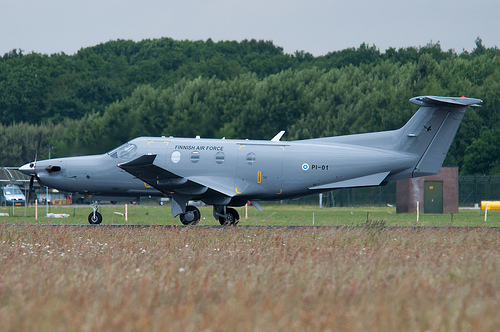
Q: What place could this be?
A: It is a forest.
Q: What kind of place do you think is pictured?
A: It is a forest.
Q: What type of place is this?
A: It is a forest.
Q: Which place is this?
A: It is a forest.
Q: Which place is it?
A: It is a forest.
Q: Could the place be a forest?
A: Yes, it is a forest.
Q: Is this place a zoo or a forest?
A: It is a forest.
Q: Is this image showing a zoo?
A: No, the picture is showing a forest.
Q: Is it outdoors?
A: Yes, it is outdoors.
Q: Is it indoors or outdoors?
A: It is outdoors.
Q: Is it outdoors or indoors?
A: It is outdoors.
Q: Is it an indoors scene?
A: No, it is outdoors.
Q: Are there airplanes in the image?
A: Yes, there is an airplane.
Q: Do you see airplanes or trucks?
A: Yes, there is an airplane.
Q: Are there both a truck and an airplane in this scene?
A: No, there is an airplane but no trucks.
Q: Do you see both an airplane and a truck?
A: No, there is an airplane but no trucks.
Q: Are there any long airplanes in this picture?
A: Yes, there is a long airplane.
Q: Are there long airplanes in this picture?
A: Yes, there is a long airplane.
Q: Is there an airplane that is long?
A: Yes, there is an airplane that is long.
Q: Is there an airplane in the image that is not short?
A: Yes, there is a long airplane.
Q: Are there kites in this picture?
A: No, there are no kites.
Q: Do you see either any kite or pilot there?
A: No, there are no kites or pilots.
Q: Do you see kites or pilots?
A: No, there are no kites or pilots.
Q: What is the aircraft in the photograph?
A: The aircraft is an airplane.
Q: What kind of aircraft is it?
A: The aircraft is an airplane.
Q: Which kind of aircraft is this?
A: That is an airplane.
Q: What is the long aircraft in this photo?
A: The aircraft is an airplane.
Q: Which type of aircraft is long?
A: The aircraft is an airplane.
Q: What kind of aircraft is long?
A: The aircraft is an airplane.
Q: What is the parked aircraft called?
A: The aircraft is an airplane.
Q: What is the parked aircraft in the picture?
A: The aircraft is an airplane.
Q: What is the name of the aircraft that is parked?
A: The aircraft is an airplane.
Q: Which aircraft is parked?
A: The aircraft is an airplane.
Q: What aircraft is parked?
A: The aircraft is an airplane.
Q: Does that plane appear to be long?
A: Yes, the plane is long.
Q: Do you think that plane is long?
A: Yes, the plane is long.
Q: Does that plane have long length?
A: Yes, the plane is long.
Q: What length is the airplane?
A: The airplane is long.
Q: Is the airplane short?
A: No, the airplane is long.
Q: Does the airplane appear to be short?
A: No, the airplane is long.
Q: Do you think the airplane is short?
A: No, the airplane is long.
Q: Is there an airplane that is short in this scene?
A: No, there is an airplane but it is long.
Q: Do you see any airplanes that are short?
A: No, there is an airplane but it is long.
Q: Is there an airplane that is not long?
A: No, there is an airplane but it is long.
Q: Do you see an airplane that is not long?
A: No, there is an airplane but it is long.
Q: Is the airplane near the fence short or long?
A: The plane is long.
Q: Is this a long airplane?
A: Yes, this is a long airplane.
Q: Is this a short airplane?
A: No, this is a long airplane.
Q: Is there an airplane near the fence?
A: Yes, there is an airplane near the fence.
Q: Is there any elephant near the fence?
A: No, there is an airplane near the fence.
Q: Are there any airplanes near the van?
A: Yes, there is an airplane near the van.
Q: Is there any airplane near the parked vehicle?
A: Yes, there is an airplane near the van.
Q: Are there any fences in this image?
A: Yes, there is a fence.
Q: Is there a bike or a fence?
A: Yes, there is a fence.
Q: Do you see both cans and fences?
A: No, there is a fence but no cans.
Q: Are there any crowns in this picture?
A: No, there are no crowns.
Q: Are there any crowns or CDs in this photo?
A: No, there are no crowns or cds.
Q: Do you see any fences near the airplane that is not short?
A: Yes, there is a fence near the airplane.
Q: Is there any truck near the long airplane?
A: No, there is a fence near the plane.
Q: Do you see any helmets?
A: No, there are no helmets.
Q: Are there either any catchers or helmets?
A: No, there are no helmets or catchers.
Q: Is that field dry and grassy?
A: Yes, the field is dry and grassy.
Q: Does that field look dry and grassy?
A: Yes, the field is dry and grassy.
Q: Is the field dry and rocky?
A: No, the field is dry but grassy.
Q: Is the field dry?
A: Yes, the field is dry.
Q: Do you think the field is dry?
A: Yes, the field is dry.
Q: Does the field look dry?
A: Yes, the field is dry.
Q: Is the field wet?
A: No, the field is dry.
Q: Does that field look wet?
A: No, the field is dry.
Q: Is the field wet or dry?
A: The field is dry.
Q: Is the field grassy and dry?
A: Yes, the field is grassy and dry.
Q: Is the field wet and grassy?
A: No, the field is grassy but dry.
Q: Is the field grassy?
A: Yes, the field is grassy.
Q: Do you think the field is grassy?
A: Yes, the field is grassy.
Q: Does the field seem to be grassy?
A: Yes, the field is grassy.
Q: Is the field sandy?
A: No, the field is grassy.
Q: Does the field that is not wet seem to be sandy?
A: No, the field is grassy.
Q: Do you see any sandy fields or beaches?
A: No, there is a field but it is grassy.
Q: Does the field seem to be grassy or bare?
A: The field is grassy.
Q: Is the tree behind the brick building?
A: Yes, the tree is behind the building.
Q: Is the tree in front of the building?
A: No, the tree is behind the building.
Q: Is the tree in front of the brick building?
A: No, the tree is behind the building.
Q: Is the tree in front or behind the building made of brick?
A: The tree is behind the building.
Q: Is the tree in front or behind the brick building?
A: The tree is behind the building.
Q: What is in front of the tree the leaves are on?
A: The building is in front of the tree.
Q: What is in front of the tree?
A: The building is in front of the tree.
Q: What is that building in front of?
A: The building is in front of the tree.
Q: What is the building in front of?
A: The building is in front of the tree.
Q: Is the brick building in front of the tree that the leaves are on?
A: Yes, the building is in front of the tree.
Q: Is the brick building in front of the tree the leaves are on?
A: Yes, the building is in front of the tree.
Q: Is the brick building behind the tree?
A: No, the building is in front of the tree.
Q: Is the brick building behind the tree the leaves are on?
A: No, the building is in front of the tree.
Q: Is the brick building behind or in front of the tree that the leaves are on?
A: The building is in front of the tree.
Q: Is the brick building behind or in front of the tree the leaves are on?
A: The building is in front of the tree.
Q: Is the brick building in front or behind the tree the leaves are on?
A: The building is in front of the tree.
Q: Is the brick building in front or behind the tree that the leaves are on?
A: The building is in front of the tree.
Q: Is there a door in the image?
A: Yes, there is a door.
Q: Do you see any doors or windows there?
A: Yes, there is a door.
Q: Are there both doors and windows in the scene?
A: Yes, there are both a door and a window.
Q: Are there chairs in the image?
A: No, there are no chairs.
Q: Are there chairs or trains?
A: No, there are no chairs or trains.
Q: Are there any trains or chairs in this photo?
A: No, there are no chairs or trains.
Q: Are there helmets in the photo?
A: No, there are no helmets.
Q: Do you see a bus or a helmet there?
A: No, there are no helmets or buses.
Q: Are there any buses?
A: No, there are no buses.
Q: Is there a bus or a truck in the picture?
A: No, there are no buses or trucks.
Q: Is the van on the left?
A: Yes, the van is on the left of the image.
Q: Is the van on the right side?
A: No, the van is on the left of the image.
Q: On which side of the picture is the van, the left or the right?
A: The van is on the left of the image.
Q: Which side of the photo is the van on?
A: The van is on the left of the image.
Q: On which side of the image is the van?
A: The van is on the left of the image.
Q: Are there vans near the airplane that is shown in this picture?
A: Yes, there is a van near the airplane.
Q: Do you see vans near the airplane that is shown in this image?
A: Yes, there is a van near the airplane.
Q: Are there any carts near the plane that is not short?
A: No, there is a van near the plane.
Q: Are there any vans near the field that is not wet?
A: Yes, there is a van near the field.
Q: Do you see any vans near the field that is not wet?
A: Yes, there is a van near the field.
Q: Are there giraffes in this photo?
A: No, there are no giraffes.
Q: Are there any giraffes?
A: No, there are no giraffes.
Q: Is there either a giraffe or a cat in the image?
A: No, there are no giraffes or cats.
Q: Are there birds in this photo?
A: No, there are no birds.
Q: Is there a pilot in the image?
A: No, there are no pilots.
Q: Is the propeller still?
A: Yes, the propeller is still.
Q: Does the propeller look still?
A: Yes, the propeller is still.